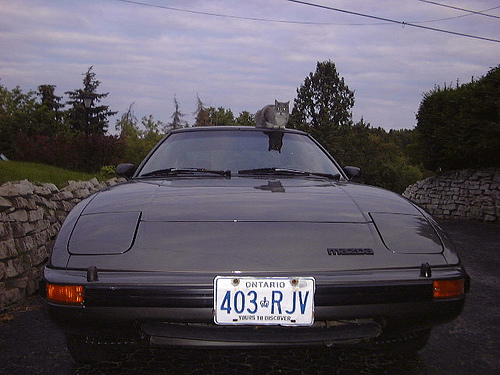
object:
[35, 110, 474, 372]
car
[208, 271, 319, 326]
license plate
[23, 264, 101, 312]
headlights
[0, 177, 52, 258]
walls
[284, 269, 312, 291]
crown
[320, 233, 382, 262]
brand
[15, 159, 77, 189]
grass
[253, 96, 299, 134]
cat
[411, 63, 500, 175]
hedge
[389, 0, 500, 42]
lines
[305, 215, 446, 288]
logo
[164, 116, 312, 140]
roof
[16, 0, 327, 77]
sky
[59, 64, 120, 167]
trees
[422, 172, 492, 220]
wall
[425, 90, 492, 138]
bushes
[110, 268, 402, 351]
bumper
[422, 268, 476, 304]
light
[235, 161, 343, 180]
wipers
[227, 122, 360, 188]
top